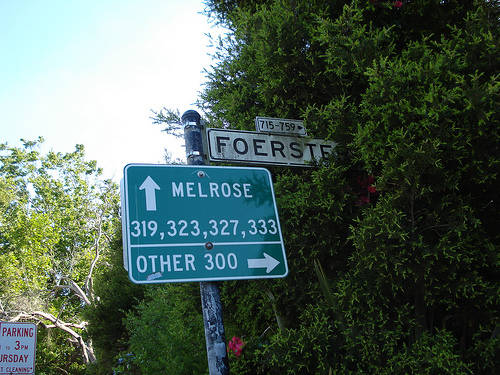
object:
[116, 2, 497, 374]
trees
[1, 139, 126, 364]
tree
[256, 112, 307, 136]
sign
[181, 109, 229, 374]
pole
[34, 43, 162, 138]
cloud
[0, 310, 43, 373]
sign letters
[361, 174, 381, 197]
objects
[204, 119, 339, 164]
street sign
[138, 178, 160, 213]
arrow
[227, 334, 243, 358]
pink object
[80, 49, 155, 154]
clouds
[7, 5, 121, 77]
sky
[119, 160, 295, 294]
sign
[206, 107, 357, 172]
sign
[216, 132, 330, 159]
letters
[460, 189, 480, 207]
part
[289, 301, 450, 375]
bush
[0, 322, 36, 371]
parking sign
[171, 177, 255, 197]
letters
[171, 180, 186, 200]
letters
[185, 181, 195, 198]
letters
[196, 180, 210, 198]
letters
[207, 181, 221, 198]
letters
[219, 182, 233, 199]
letters